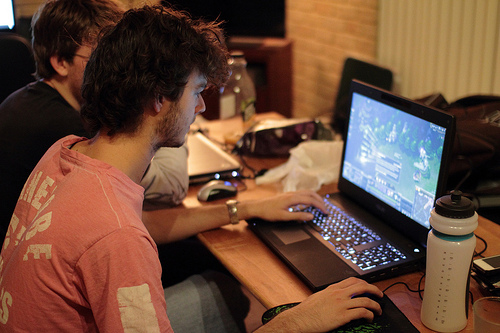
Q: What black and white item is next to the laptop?
A: A water bottle.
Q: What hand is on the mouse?
A: The right hand.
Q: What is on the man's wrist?
A: A watch.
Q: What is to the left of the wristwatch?
A: A mouse.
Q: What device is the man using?
A: A laptop.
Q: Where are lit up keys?
A: On laptop.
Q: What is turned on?
A: Laptop screen.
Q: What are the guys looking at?
A: The laptop screen.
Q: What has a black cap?
A: White thermos.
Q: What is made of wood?
A: The table.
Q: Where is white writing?
A: On faded red shirt.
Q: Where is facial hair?
A: On man's face.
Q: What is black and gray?
A: Computer mouse.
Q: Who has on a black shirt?
A: Guy on the left.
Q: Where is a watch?
A: Around man's left wrist.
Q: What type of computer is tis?
A: Labtop.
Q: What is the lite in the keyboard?
A: Backlit.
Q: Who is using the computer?
A: A man.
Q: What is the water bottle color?
A: White.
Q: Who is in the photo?
A: Two men.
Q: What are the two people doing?
A: Using a computer.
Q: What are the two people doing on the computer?
A: Playing a game.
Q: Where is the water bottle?
A: Next to the laptop.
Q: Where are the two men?
A: Indoors at a desk.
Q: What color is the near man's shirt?
A: Red.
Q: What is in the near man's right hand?
A: Computer mouse.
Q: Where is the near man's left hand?
A: Computer keyboard.